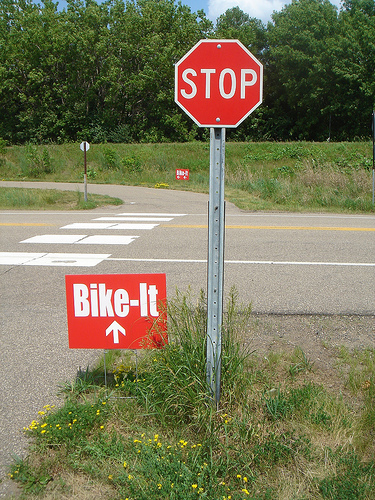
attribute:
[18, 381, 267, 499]
flowers — yellow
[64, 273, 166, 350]
sign — red, white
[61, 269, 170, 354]
sign — red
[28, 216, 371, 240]
line — double yellow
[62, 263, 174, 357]
sign — red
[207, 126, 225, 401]
pole — silver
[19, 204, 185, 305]
line — white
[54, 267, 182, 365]
sign — white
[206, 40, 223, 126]
bolts — silver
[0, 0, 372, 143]
trees — green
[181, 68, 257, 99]
lettering — white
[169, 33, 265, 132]
sign — stop, street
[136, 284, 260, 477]
bush — green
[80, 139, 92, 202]
pole — rusty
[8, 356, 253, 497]
flowers — yellow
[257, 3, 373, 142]
tree — green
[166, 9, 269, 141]
tree — green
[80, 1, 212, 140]
tree — green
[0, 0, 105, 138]
tree — green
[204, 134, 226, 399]
pole — silver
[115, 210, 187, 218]
line — white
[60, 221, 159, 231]
line — white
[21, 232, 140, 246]
line — white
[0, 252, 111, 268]
line — white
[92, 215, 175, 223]
line — white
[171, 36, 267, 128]
street sign — red, white